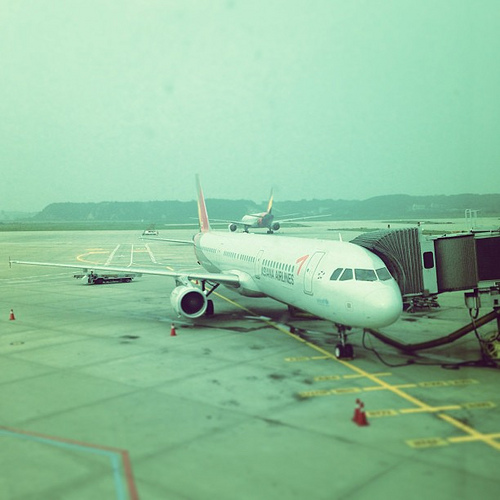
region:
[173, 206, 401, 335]
A plane in the airport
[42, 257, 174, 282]
Wings on the plane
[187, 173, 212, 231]
Tail on the plane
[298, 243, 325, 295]
A plane door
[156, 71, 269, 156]
Cloudy skies in the photo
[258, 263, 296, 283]
writing on the side of the plane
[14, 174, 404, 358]
white and red airplane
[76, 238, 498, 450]
yellow lines on the pavement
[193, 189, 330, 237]
airplane in the background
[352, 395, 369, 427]
orange cones in the foreground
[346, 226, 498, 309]
loading dock on plane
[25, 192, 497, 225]
hills in background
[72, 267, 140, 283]
luggage conveyor behind plane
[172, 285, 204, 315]
jet engine on plane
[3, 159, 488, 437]
airplane is color white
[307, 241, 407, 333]
cockpit of airplane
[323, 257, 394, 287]
windows on the cockpit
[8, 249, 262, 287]
long white wing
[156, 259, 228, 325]
engine under the wing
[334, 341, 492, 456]
yellow lines on the ground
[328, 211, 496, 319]
loading bridge on plane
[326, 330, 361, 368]
black front wheel of plane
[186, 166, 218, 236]
vertical stabilizer is red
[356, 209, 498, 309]
mobil bridge is color gray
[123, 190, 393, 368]
white plane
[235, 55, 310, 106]
white clouds in blue sky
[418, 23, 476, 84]
white clouds in blue sky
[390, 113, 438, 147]
white clouds in blue sky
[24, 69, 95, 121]
white clouds in blue sky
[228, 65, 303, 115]
white clouds in blue sky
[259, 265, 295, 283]
A logo on side of plane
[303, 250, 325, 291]
A white plane door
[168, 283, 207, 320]
A plane engine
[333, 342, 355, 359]
A plane's landing wheel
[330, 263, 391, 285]
A plane's cockpit windows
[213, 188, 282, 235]
A plane on runway in background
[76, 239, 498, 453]
Yellow strips on runway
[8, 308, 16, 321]
Orange cone on runway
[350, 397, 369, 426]
Two orange cones on runway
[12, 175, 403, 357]
A parked white plane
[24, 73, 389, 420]
this is an airport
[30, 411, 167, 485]
the lines are red and blue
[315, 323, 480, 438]
the lines are yellow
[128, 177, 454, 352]
plane is boarding passangers for flight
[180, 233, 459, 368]
plane landed and is passengers are being escorted off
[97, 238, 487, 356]
plane is grounded due to mechanical difficulties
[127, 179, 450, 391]
the pilot is going through all of the checks in the cockpit for safety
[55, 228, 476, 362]
the plane is fueling up for international flight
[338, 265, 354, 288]
A window on a vehicle.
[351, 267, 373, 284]
A window on a vehicle.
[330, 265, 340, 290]
A window on a vehicle.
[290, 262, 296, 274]
A window on a vehicle.